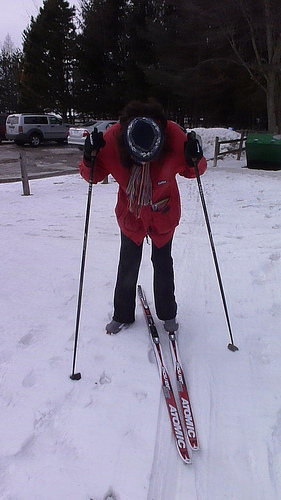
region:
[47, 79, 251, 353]
Woman looking down at the snow.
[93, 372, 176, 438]
Tracks in the snow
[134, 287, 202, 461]
Skis laying on the snow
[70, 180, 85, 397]
Ski pole in woman's hand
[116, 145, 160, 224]
Woman wearing a scarf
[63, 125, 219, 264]
Woman wearing a red coat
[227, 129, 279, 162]
Dumpster in the background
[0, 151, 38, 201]
Wooden fence in the background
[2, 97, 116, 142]
Cars parked in a lot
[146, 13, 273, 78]
Tree is missing leaves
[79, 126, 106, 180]
gloved hand on pole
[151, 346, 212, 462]
two skis on snow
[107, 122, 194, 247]
red jacket on woman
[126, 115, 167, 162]
top of woman's hat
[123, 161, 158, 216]
scarf in front of chest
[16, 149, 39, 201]
wood pole in snow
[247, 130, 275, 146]
cover of green dumpster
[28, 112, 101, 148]
two parked vehicles in lot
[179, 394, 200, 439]
white word on red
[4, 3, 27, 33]
cloud cover in sky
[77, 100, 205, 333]
A person looking down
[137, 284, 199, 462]
Red and white snow skis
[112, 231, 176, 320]
Black snow pants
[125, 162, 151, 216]
Multicolored neck scarf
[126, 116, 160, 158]
Warm, woolen beanie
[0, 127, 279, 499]
Snow covered ground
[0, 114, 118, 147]
Cars parked in parking lot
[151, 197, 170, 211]
Objects in person's pocket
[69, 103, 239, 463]
A person looking down to put on skis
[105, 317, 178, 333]
Grey ski shoes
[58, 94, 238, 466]
Skier looking down at skis.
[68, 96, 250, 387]
Skier holding ski poles.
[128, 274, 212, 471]
A pair of skis.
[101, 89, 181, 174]
A person with long hair.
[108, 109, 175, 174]
A winter toboggan.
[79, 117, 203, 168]
Black gloves on skier's hands.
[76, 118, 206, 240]
A red winter coat.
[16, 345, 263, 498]
Tracks in the snow.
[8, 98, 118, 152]
Two vehicles parked in the background.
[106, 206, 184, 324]
A pair of long dark pants.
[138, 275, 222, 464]
red skis with the word "atomic"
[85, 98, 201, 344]
woman wearing red parka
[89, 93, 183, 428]
woman wearing blue hat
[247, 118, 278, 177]
trash container in snow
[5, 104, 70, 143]
SUV in parking lot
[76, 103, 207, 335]
woman wearing grey boots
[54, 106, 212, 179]
woman grasping ski poles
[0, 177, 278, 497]
powdery snow covers ground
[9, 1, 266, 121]
large pine trees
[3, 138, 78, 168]
ski poles stuck in snow